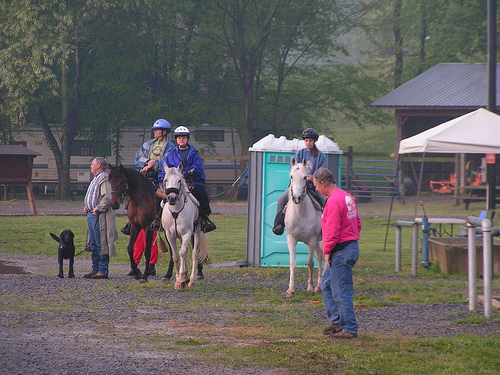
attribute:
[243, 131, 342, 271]
port-a-pottie — blue, grey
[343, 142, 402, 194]
fence — metal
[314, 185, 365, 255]
shirt — red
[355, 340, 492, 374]
grass — green, patch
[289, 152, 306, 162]
dot — small, black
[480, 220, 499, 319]
poles — metal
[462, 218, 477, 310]
poles — metal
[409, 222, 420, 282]
poles — metal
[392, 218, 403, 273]
poles — metal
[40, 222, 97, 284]
dog — black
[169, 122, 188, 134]
hemlet — white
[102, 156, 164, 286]
horse — brown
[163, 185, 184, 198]
fabric — black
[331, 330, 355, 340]
shoe — brown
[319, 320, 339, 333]
shoe — brown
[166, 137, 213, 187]
jacket — blue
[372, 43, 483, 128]
roof — metal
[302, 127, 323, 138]
helmet — blue, black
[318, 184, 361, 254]
shirt — pink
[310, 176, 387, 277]
shirt — blue, with white stripes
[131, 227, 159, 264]
fabric — red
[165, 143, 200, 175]
jacket — blue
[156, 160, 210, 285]
horse — white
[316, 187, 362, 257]
shirt — pink, orange